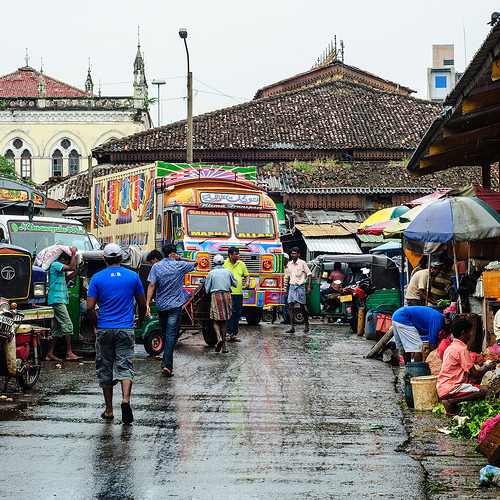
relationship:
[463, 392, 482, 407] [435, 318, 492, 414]
lettuce next to boy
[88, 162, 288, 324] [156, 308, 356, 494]
bus in road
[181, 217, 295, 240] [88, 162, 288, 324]
windshield of bus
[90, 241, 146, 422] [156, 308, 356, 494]
man on road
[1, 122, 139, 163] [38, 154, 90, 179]
arches over window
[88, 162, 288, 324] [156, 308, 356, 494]
bus on road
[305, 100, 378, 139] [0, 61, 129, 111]
shingles on roof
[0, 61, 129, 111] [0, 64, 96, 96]
roof has roof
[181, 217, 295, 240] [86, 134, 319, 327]
windshield of bus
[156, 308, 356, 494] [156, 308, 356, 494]
road over road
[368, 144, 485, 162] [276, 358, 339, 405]
umbrella due to rain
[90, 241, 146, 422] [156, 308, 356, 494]
man in road